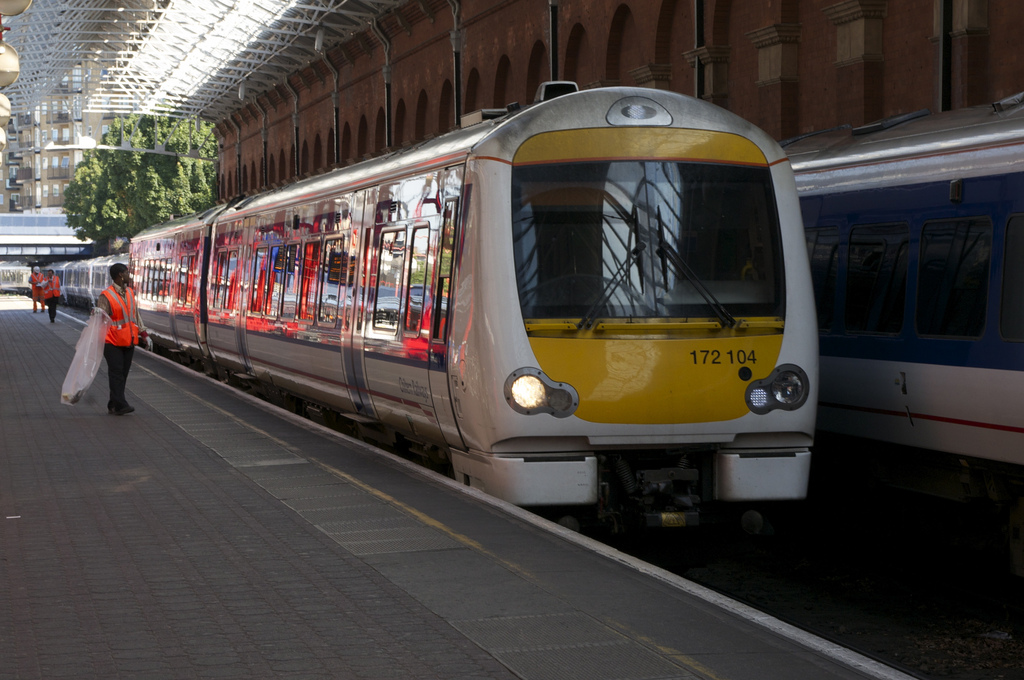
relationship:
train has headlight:
[117, 67, 831, 525] [501, 362, 549, 421]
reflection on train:
[117, 153, 470, 383] [117, 67, 831, 525]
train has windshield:
[117, 67, 831, 525] [512, 160, 791, 327]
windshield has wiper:
[497, 127, 794, 331] [560, 220, 660, 331]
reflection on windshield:
[586, 146, 693, 317] [512, 160, 791, 327]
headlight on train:
[601, 93, 675, 133] [117, 67, 831, 525]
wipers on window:
[572, 231, 739, 324] [497, 157, 791, 343]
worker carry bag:
[98, 253, 148, 418] [51, 300, 114, 415]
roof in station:
[17, 0, 355, 117] [8, 9, 1022, 675]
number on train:
[682, 339, 762, 372] [117, 67, 831, 525]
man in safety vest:
[41, 269, 189, 410] [95, 289, 139, 356]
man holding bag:
[41, 269, 189, 410] [51, 309, 103, 383]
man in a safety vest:
[41, 269, 189, 410] [95, 289, 139, 356]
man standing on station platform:
[41, 269, 189, 410] [2, 289, 947, 668]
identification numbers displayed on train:
[676, 330, 765, 382] [117, 67, 831, 525]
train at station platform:
[117, 67, 831, 525] [2, 289, 947, 668]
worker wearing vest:
[84, 252, 158, 415] [91, 289, 143, 352]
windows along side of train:
[87, 170, 463, 356] [117, 67, 831, 525]